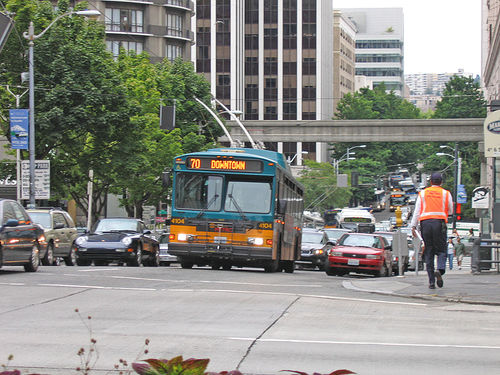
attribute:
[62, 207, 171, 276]
porsche — black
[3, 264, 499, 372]
road — vehicle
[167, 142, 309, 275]
vehicle — blue, yellow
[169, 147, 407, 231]
near bus — red car